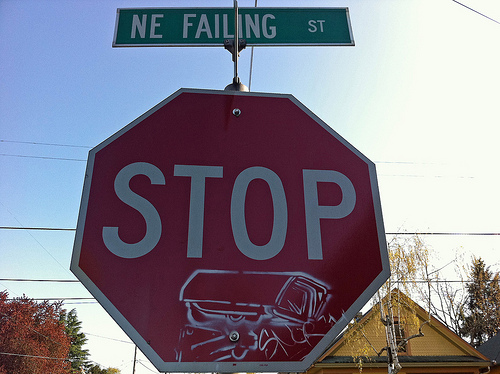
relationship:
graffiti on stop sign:
[178, 269, 347, 361] [70, 87, 391, 373]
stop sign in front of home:
[70, 87, 391, 373] [277, 287, 496, 372]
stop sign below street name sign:
[70, 87, 391, 373] [111, 6, 355, 47]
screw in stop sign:
[231, 106, 242, 118] [70, 87, 391, 373]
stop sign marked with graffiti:
[70, 87, 391, 373] [178, 269, 347, 361]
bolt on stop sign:
[227, 330, 240, 343] [70, 87, 391, 373]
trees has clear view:
[1, 289, 119, 372] [2, 288, 114, 371]